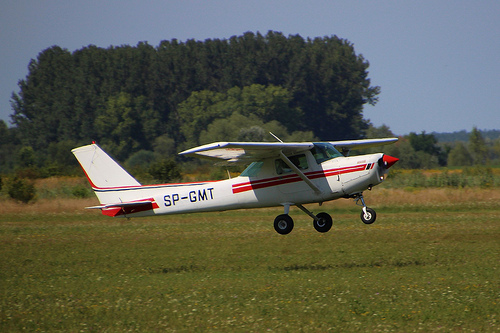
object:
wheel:
[271, 214, 297, 243]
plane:
[76, 130, 390, 247]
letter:
[161, 186, 214, 209]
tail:
[66, 140, 143, 218]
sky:
[31, 11, 253, 54]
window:
[274, 151, 311, 175]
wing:
[78, 201, 154, 219]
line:
[230, 159, 376, 196]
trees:
[386, 122, 500, 167]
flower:
[162, 268, 409, 329]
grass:
[29, 197, 428, 320]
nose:
[378, 151, 400, 169]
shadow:
[266, 247, 438, 286]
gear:
[269, 211, 333, 236]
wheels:
[311, 208, 380, 234]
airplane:
[67, 130, 400, 237]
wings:
[176, 129, 314, 168]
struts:
[279, 156, 329, 197]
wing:
[316, 137, 400, 151]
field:
[20, 225, 459, 312]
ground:
[63, 238, 437, 305]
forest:
[33, 40, 453, 179]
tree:
[1, 35, 108, 205]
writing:
[163, 187, 215, 208]